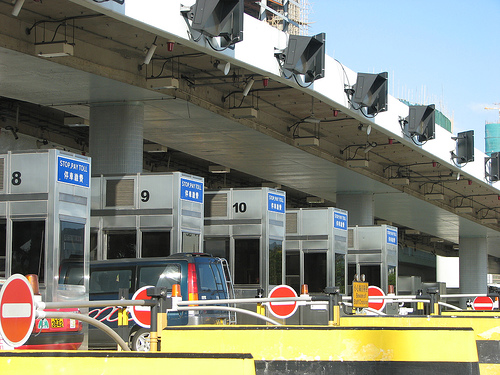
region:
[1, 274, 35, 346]
Red do not enter sign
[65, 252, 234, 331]
Van entering a toll road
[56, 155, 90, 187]
Blue sign on a toll booth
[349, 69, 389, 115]
Speaker over a toll station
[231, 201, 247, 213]
10 on side of a toll booth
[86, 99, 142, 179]
Pillar on a toll station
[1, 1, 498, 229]
Roof of a tool station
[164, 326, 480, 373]
Barrier in front of a toll station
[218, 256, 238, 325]
Ladder on the back of a van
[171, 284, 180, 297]
Light on a toll booth gate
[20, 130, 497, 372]
this is a toll booth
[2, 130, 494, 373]
this is a toll crossing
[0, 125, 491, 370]
here is a line of toll booths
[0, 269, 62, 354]
this is a round sign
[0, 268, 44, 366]
this sign is red and white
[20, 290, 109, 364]
the rear of a red car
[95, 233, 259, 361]
this is a blue van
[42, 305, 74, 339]
this is a yellow license plate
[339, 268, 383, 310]
this sign is yellow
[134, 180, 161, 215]
the number 9 is in black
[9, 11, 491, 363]
Closeup of a row of tollbooths.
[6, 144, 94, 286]
Toll booth number 8.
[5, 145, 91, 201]
Blue and white sign on tollbooth 8.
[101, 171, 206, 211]
Blue and white sign on tollbooth 9.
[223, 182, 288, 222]
Blue and white sign on tollbooth 10.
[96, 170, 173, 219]
Vent on tollbooth 9.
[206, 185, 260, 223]
Vent on toll booth 10.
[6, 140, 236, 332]
A dark colored vehicle between booth 8 and 9.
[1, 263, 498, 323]
Round signs on all of the gates.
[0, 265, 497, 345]
Red and white signs on all of the gates.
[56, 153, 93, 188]
The sign on the front of the stand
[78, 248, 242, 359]
The van going into the parking lot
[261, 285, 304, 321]
The sign is red and white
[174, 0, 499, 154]
The sky is clear and blue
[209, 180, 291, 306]
The number "10" parking stall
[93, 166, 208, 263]
The number "9" parking stall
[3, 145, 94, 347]
The number "8" parking stall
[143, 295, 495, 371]
The yellow construction lanes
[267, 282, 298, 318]
sign red and white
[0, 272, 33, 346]
sign is a circle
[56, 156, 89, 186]
white and blue sign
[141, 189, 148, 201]
number 9 on booth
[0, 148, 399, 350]
a series of booths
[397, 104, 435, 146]
light on the wall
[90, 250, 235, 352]
the van is stopped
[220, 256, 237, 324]
ladder on the van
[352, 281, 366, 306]
yellow and black sign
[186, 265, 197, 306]
reflectors on the van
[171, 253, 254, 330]
back of the van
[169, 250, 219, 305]
red light on back of van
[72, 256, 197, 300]
side windows on van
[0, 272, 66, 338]
red and white sign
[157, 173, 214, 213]
blue sign on booth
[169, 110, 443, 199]
area above the booths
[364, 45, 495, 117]
light sky above building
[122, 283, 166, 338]
a sign on the pole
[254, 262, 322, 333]
a sign on the pole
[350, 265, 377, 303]
a sign on the pole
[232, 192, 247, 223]
a number on the station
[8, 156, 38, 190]
a number on the station